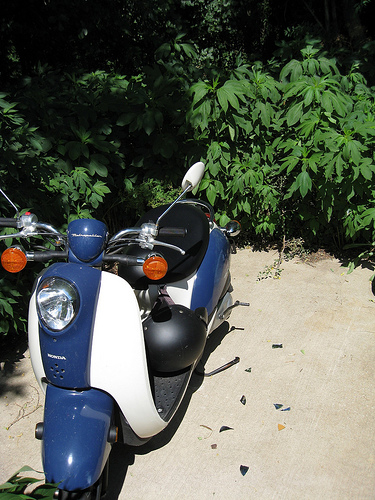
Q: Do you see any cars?
A: No, there are no cars.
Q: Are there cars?
A: No, there are no cars.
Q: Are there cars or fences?
A: No, there are no cars or fences.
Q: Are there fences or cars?
A: No, there are no cars or fences.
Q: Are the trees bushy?
A: Yes, the trees are bushy.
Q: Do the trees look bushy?
A: Yes, the trees are bushy.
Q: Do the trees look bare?
A: No, the trees are bushy.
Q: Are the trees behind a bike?
A: Yes, the trees are behind a bike.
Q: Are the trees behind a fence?
A: No, the trees are behind a bike.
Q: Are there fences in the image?
A: No, there are no fences.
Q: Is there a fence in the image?
A: No, there are no fences.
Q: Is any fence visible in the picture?
A: No, there are no fences.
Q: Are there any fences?
A: No, there are no fences.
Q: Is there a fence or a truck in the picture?
A: No, there are no fences or trucks.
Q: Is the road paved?
A: Yes, the road is paved.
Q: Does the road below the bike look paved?
A: Yes, the road is paved.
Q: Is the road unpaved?
A: No, the road is paved.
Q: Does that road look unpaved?
A: No, the road is paved.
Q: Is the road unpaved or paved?
A: The road is paved.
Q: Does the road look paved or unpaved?
A: The road is paved.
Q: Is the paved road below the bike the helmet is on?
A: Yes, the road is below the bike.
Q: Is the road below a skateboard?
A: No, the road is below the bike.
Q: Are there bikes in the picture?
A: Yes, there is a bike.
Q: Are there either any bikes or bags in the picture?
A: Yes, there is a bike.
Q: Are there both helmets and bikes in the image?
A: Yes, there are both a bike and a helmet.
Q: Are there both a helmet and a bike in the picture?
A: Yes, there are both a bike and a helmet.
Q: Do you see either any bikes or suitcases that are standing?
A: Yes, the bike is standing.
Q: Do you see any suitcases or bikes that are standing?
A: Yes, the bike is standing.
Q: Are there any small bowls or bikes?
A: Yes, there is a small bike.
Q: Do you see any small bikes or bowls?
A: Yes, there is a small bike.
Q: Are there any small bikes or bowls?
A: Yes, there is a small bike.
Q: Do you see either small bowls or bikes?
A: Yes, there is a small bike.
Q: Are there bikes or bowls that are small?
A: Yes, the bike is small.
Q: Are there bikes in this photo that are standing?
A: Yes, there is a bike that is standing.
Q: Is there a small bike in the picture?
A: Yes, there is a small bike.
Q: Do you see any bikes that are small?
A: Yes, there is a small bike.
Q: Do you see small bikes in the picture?
A: Yes, there is a small bike.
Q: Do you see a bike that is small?
A: Yes, there is a bike that is small.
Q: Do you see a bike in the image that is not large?
A: Yes, there is a small bike.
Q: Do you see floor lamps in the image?
A: No, there are no floor lamps.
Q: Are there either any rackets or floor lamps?
A: No, there are no floor lamps or rackets.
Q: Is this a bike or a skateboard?
A: This is a bike.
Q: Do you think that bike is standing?
A: Yes, the bike is standing.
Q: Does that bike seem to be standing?
A: Yes, the bike is standing.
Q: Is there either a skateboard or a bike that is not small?
A: No, there is a bike but it is small.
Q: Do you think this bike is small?
A: Yes, the bike is small.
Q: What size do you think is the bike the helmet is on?
A: The bike is small.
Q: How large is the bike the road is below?
A: The bike is small.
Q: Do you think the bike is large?
A: No, the bike is small.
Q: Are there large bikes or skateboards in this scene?
A: No, there is a bike but it is small.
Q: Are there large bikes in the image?
A: No, there is a bike but it is small.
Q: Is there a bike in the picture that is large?
A: No, there is a bike but it is small.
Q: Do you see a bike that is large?
A: No, there is a bike but it is small.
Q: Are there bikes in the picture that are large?
A: No, there is a bike but it is small.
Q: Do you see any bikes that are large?
A: No, there is a bike but it is small.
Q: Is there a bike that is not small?
A: No, there is a bike but it is small.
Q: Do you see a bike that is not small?
A: No, there is a bike but it is small.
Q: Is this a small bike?
A: Yes, this is a small bike.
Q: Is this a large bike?
A: No, this is a small bike.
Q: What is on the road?
A: The bike is on the road.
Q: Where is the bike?
A: The bike is on the road.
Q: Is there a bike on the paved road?
A: Yes, there is a bike on the road.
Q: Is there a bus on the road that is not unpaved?
A: No, there is a bike on the road.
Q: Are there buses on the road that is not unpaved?
A: No, there is a bike on the road.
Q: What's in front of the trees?
A: The bike is in front of the trees.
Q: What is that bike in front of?
A: The bike is in front of the trees.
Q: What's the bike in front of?
A: The bike is in front of the trees.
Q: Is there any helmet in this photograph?
A: Yes, there is a helmet.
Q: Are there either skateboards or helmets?
A: Yes, there is a helmet.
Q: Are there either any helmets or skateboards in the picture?
A: Yes, there is a helmet.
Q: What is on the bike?
A: The helmet is on the bike.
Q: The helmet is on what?
A: The helmet is on the bike.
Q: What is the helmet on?
A: The helmet is on the bike.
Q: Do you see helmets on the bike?
A: Yes, there is a helmet on the bike.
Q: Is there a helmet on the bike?
A: Yes, there is a helmet on the bike.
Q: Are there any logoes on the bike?
A: No, there is a helmet on the bike.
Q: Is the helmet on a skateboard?
A: No, the helmet is on the bike.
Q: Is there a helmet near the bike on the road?
A: Yes, there is a helmet near the bike.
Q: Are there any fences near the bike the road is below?
A: No, there is a helmet near the bike.